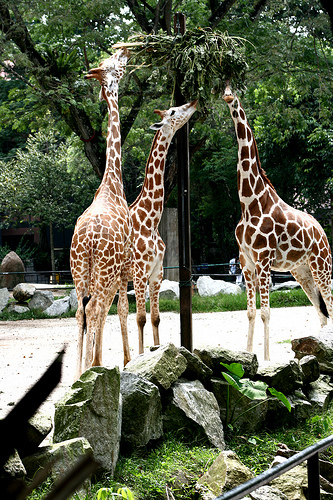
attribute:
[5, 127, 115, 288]
tree — green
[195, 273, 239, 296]
rock — white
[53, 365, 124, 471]
stone — grey, big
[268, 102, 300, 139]
tree leaves — green 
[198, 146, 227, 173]
tree leaves — green 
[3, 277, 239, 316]
rocks — a set, in the background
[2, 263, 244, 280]
fence — black, metal, in the background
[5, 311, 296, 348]
area — concrete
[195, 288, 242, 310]
grass — a set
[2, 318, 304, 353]
area — concrete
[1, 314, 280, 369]
area — concrete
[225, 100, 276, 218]
neck — long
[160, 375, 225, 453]
rock — gray